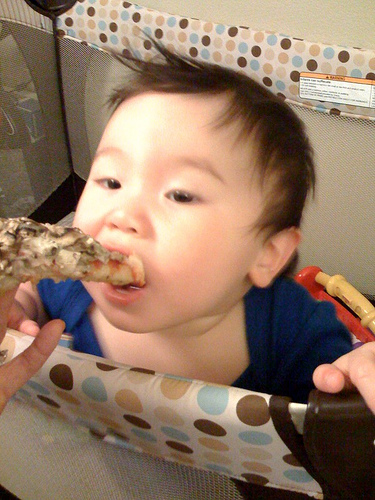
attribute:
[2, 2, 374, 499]
playpin — brown, dotted, patterned, mesh, decorated, polka dot, bedded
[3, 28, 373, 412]
baby — standing, eating, small, decorated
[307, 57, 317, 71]
dot — dark brown, blue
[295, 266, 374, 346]
toy — yellow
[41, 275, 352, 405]
shirt — blue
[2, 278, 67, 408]
person — feeding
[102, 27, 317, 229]
hair — black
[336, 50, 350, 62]
spot — brown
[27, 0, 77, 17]
corner — plastice, brown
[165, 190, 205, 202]
eye — black, open